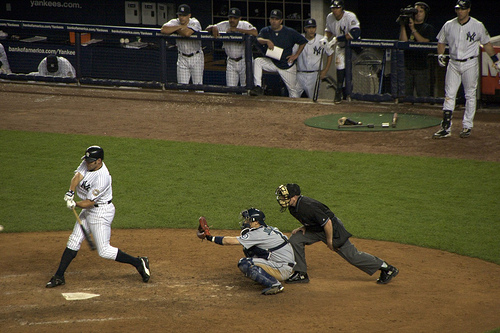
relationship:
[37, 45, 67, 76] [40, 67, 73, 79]
player wearing uniform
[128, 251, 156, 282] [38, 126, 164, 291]
shoe on batter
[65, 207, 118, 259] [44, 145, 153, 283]
pinstripes on baseball batter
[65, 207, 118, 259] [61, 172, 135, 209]
pinstripes on jersey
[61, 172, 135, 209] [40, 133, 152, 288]
jersey on batter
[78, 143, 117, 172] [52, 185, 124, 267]
helmet on batter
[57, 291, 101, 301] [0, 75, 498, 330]
plate on field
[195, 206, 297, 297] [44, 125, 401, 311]
catcher in game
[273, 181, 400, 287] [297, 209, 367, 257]
umpire in clothing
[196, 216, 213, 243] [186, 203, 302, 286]
mitt on catcher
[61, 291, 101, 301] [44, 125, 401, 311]
home plate of a game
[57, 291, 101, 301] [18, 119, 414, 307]
plate of a game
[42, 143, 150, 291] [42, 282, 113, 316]
batter at plate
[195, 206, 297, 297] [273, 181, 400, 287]
catcher with umpire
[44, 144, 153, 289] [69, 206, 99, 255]
baseball batter up at bat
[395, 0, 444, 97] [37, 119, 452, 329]
cameraman filming game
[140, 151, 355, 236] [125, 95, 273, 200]
turf on field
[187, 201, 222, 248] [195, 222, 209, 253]
glove in hand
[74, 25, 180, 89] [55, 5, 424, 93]
railing in pen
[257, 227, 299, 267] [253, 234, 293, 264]
strap around waist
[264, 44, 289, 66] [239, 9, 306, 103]
paper in hand of man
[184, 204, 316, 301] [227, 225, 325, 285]
player wearing uniform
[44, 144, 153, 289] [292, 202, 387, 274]
baseball batter wearing uniform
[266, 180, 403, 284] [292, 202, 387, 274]
baseball player wearing uniform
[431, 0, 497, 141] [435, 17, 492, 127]
player uniform wearing uniform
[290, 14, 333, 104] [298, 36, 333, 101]
player wearing uniform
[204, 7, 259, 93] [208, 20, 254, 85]
baseball player wearing uniform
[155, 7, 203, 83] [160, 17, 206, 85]
baseball player wearing uniform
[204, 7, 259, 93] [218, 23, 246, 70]
baseball player wearing uniform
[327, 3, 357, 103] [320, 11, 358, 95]
player wearing uniform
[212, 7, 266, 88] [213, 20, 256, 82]
baseball player wearing uniform